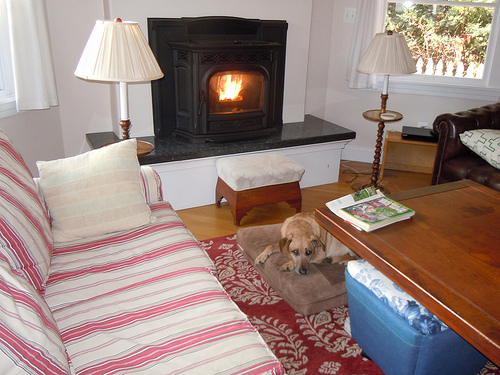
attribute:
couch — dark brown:
[424, 95, 499, 193]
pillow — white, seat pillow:
[31, 127, 168, 264]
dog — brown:
[245, 203, 353, 278]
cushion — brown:
[232, 224, 356, 326]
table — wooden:
[416, 181, 480, 279]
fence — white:
[425, 51, 480, 73]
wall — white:
[54, 8, 93, 29]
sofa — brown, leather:
[429, 94, 496, 190]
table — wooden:
[341, 194, 499, 314]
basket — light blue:
[342, 259, 490, 374]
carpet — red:
[198, 224, 383, 374]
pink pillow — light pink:
[41, 136, 161, 247]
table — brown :
[319, 180, 499, 360]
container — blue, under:
[342, 257, 488, 374]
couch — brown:
[429, 87, 499, 188]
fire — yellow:
[215, 70, 245, 101]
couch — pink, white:
[0, 131, 285, 371]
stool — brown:
[224, 164, 309, 214]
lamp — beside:
[72, 5, 195, 185]